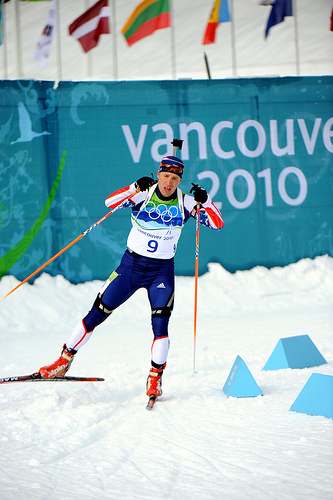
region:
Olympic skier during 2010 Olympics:
[0, 149, 233, 415]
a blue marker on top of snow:
[220, 318, 260, 408]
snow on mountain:
[5, 271, 264, 486]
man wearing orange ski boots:
[0, 352, 170, 392]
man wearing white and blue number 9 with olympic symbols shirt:
[102, 151, 190, 259]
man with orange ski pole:
[189, 185, 205, 374]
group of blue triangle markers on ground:
[224, 328, 332, 416]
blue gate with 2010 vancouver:
[3, 50, 330, 197]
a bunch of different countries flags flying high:
[16, 0, 330, 71]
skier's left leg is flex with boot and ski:
[1, 243, 139, 386]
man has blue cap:
[154, 144, 186, 177]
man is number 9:
[138, 196, 170, 264]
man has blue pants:
[108, 246, 186, 330]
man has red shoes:
[142, 369, 167, 396]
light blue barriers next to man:
[229, 333, 266, 415]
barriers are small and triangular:
[217, 344, 265, 402]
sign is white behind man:
[113, 114, 328, 230]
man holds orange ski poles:
[160, 195, 207, 343]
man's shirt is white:
[122, 196, 180, 272]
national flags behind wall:
[27, 10, 290, 70]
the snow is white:
[76, 397, 178, 495]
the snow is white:
[134, 416, 224, 494]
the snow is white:
[170, 433, 233, 487]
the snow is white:
[164, 451, 201, 490]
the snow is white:
[144, 427, 200, 488]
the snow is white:
[106, 450, 173, 492]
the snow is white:
[154, 464, 175, 491]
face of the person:
[143, 148, 182, 199]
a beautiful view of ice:
[4, 392, 295, 498]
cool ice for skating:
[9, 385, 332, 492]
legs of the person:
[74, 290, 175, 385]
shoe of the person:
[32, 350, 84, 385]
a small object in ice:
[222, 342, 261, 410]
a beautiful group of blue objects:
[227, 339, 332, 443]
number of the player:
[139, 225, 172, 263]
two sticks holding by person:
[47, 203, 256, 305]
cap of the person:
[160, 157, 187, 174]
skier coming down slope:
[36, 132, 217, 430]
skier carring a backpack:
[125, 178, 211, 246]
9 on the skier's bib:
[143, 231, 162, 266]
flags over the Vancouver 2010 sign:
[56, 28, 326, 77]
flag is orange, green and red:
[125, 6, 185, 49]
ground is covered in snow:
[60, 421, 227, 467]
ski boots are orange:
[52, 351, 189, 395]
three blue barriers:
[222, 328, 318, 435]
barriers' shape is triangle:
[190, 338, 326, 424]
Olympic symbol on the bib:
[132, 195, 189, 231]